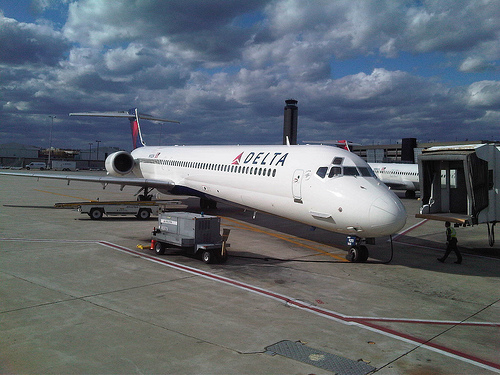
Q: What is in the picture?
A: An airplane.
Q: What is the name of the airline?
A: Delta.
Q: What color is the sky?
A: Blue.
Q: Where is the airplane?
A: The runway.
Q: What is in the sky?
A: Clouds.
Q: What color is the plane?
A: White.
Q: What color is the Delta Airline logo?
A: Red.